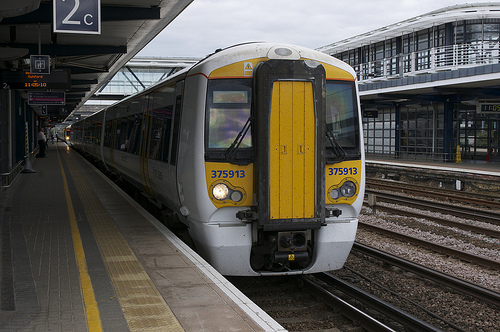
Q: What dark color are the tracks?
A: Brown.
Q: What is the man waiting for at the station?
A: Train.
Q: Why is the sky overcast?
A: It's going to rain.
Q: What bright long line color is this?
A: Yellow.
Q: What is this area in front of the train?
A: Waiting area.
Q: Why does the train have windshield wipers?
A: To move the rain.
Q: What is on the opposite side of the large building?
A: Metro station.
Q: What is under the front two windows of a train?
A: Set of numbers.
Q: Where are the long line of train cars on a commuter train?
A: Metro station.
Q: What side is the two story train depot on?
A: Right side.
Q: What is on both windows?
A: Wipers blades.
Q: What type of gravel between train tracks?
A: White rocks.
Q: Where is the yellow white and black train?
A: On track.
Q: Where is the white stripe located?
A: On edge.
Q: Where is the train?
A: Train station.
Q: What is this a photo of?
A: Train.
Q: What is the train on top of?
A: Tracks.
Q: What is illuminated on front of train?
A: Light.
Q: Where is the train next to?
A: Platform.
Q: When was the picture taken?
A: Daytime.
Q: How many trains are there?
A: One.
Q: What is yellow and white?
A: Train.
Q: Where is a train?
A: On train tracks.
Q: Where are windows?
A: On a train.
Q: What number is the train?
A: 375913.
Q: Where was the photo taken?
A: Train station.